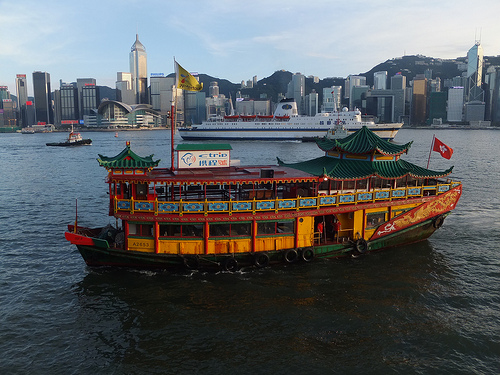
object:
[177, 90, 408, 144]
boat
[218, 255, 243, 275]
tire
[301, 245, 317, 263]
tire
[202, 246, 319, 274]
row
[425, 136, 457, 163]
flag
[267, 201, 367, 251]
door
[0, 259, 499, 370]
water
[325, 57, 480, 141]
building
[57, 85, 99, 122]
building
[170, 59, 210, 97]
flag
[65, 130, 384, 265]
tall building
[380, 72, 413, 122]
building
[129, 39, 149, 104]
building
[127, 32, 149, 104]
tall building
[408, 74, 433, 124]
tall building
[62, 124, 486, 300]
boat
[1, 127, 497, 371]
river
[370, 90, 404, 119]
wall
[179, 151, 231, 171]
advertisement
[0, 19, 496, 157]
city